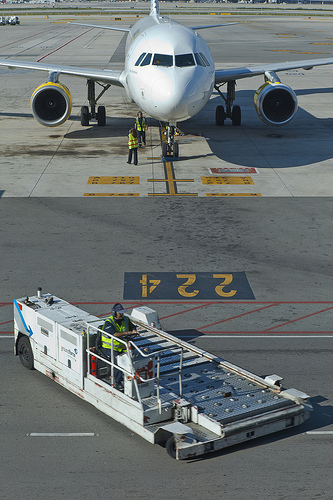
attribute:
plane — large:
[1, 3, 331, 176]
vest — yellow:
[121, 133, 146, 152]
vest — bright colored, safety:
[100, 315, 130, 351]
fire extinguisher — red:
[84, 344, 101, 379]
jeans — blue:
[101, 346, 122, 389]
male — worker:
[107, 299, 129, 354]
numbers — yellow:
[207, 172, 255, 184]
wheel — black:
[149, 136, 195, 170]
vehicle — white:
[5, 283, 318, 464]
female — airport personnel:
[124, 125, 140, 167]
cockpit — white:
[143, 30, 206, 83]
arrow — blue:
[10, 303, 36, 342]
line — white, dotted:
[25, 432, 100, 439]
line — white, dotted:
[302, 430, 332, 437]